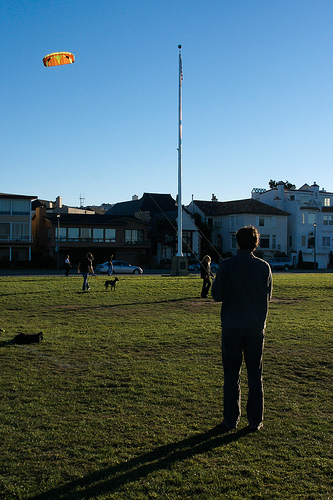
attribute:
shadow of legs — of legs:
[30, 417, 258, 499]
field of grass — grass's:
[1, 272, 332, 499]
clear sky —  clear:
[0, 0, 331, 209]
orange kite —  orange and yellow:
[39, 46, 82, 74]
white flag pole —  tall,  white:
[175, 40, 183, 255]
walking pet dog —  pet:
[72, 250, 123, 297]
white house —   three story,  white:
[187, 192, 287, 270]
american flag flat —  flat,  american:
[176, 48, 184, 100]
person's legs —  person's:
[216, 327, 269, 429]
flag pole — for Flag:
[173, 42, 185, 256]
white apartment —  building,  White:
[186, 191, 287, 263]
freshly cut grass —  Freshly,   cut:
[3, 275, 331, 498]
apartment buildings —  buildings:
[1, 183, 332, 272]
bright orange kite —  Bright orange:
[38, 47, 76, 67]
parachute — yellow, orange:
[38, 51, 82, 69]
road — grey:
[11, 268, 189, 275]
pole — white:
[173, 42, 187, 281]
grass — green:
[16, 281, 332, 486]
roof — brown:
[190, 191, 279, 224]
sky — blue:
[6, 9, 324, 174]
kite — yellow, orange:
[37, 42, 79, 74]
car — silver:
[96, 254, 144, 274]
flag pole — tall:
[170, 35, 188, 277]